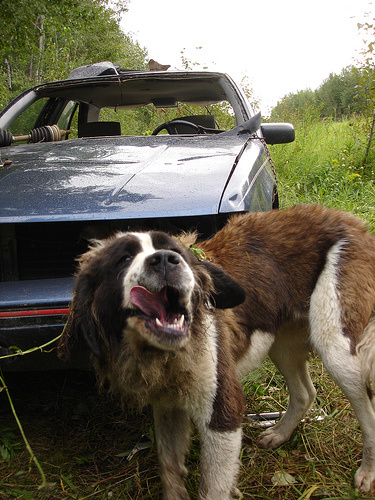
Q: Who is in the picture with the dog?
A: No on.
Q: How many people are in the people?
A: None.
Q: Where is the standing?
A: In front of a car.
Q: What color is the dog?
A: Brown and white.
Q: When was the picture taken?
A: During the day.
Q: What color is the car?
A: Blue.